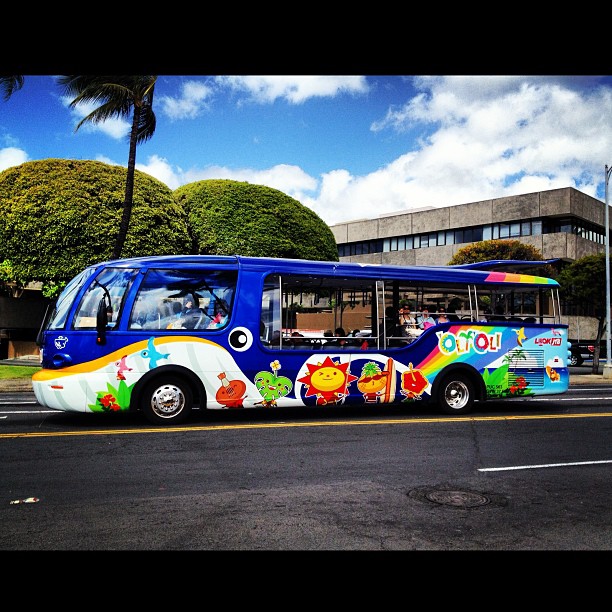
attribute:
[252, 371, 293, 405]
heart — GREEN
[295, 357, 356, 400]
sun — yellow, red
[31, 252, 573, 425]
bus — BLUE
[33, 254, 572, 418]
sun — DECAL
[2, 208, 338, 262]
tree — PALM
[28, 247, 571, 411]
bus — colorful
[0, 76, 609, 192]
sky — blue, cloudy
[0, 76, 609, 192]
clouds — white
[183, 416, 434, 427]
yellowline — long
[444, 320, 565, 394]
scene — BEACH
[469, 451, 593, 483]
line — WHITE